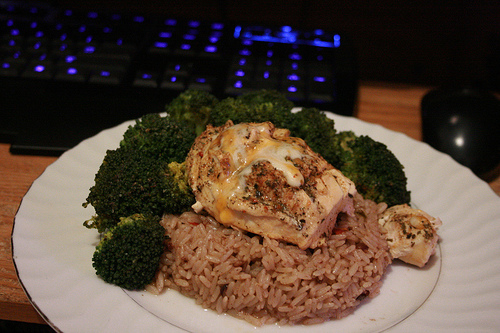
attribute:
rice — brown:
[178, 213, 344, 315]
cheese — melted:
[221, 131, 309, 193]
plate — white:
[36, 163, 200, 315]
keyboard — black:
[49, 22, 374, 109]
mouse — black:
[415, 79, 494, 178]